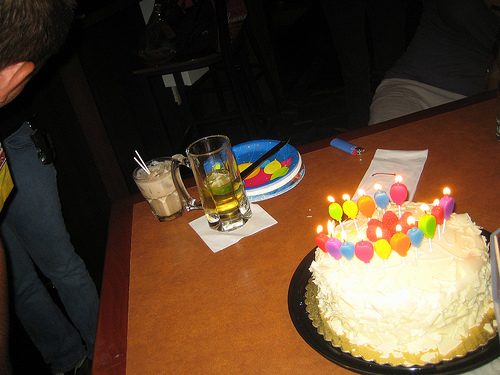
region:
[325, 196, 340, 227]
cancle next to candle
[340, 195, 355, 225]
cancle next to candle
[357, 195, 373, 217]
cancle next to candle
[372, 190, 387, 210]
cancle next to candle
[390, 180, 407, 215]
cancle next to candle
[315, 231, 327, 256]
cancle next to candle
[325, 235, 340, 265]
cancle next to candle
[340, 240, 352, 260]
cancle next to candle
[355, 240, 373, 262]
cancle next to candle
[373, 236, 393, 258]
cancle next to candle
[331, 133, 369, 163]
blue and red cigarette lighter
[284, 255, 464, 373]
black round plate holding cake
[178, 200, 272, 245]
white napkin under mug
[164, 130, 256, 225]
large clear beer mug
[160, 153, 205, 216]
clear handle on beer mug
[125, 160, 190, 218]
glass filled with brown liquid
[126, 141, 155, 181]
white straw in glass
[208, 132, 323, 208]
stack of blue paper plates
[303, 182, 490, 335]
large white coconut cake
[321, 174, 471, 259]
candles on top of cake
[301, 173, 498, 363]
a cake with many candles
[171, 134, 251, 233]
beer in a mug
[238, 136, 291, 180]
a knife on plates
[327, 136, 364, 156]
a light blue lighter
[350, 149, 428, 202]
a thin piece of paper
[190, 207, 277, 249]
a thin white napkin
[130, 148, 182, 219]
drink in a glass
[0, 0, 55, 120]
back of a man's head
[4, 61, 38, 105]
ear of a man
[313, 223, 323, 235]
flame on a candle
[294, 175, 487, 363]
Cream cake with candles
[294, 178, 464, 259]
Lighted candles on the top of the cake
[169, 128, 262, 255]
beer on the top of the napkin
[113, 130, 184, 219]
full glass of drinks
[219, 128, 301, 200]
birthday plates with knife on the top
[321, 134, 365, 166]
cigarette lighter on the top of the table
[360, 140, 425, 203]
paper on the top of the table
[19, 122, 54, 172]
Sunglasses on the side pocket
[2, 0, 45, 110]
man's head looking at the floor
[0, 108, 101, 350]
Person standing wearing blue jeans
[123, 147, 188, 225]
a glass on the table top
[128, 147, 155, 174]
the white straws in the cup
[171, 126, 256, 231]
a glass mug with liquid in it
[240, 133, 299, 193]
a knife on the paper plate stack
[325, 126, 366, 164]
the blue lighter on the table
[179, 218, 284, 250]
the napkin under the mug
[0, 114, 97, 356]
the jean pants on the person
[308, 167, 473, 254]
the candles on top of the cake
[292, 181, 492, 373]
the cake on the table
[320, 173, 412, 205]
the flame form the fire on the candles